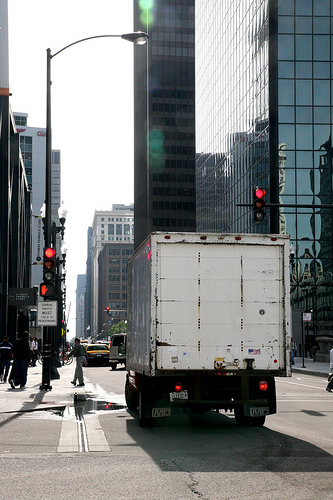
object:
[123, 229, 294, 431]
truck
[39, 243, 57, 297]
traffic light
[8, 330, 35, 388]
people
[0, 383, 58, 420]
sidewalk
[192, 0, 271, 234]
building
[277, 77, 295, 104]
glass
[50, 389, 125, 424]
puddle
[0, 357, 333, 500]
street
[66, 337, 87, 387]
man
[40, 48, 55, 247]
pole